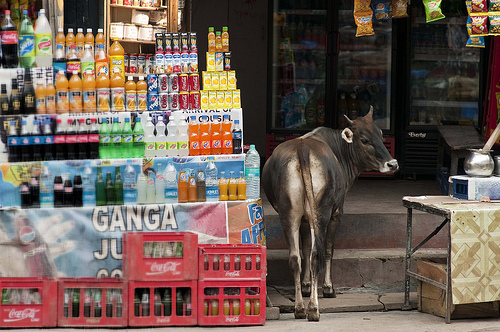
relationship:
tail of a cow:
[282, 142, 329, 264] [244, 91, 414, 329]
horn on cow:
[341, 110, 352, 122] [260, 105, 399, 322]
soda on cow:
[1, 1, 246, 201] [260, 105, 399, 322]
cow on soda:
[260, 105, 399, 322] [42, 71, 142, 107]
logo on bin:
[222, 267, 245, 278] [196, 243, 270, 289]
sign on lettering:
[3, 200, 228, 306] [90, 199, 182, 232]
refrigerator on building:
[265, 0, 402, 180] [16, 0, 376, 249]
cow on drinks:
[260, 105, 399, 322] [0, 1, 265, 323]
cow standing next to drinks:
[251, 82, 395, 302] [20, 42, 257, 297]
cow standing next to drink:
[260, 105, 399, 322] [240, 142, 265, 197]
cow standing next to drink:
[260, 105, 399, 322] [111, 162, 124, 203]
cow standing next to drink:
[260, 105, 399, 322] [107, 37, 126, 90]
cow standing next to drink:
[260, 105, 399, 322] [35, 9, 55, 69]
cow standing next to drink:
[260, 105, 399, 322] [50, 164, 64, 206]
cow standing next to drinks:
[260, 105, 399, 322] [2, 3, 262, 200]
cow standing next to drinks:
[260, 105, 399, 322] [31, 29, 237, 290]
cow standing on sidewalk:
[260, 105, 399, 322] [279, 289, 427, 326]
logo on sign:
[9, 222, 36, 246] [6, 305, 49, 323]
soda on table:
[98, 114, 112, 156] [10, 200, 271, 300]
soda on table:
[108, 115, 120, 157] [10, 200, 271, 300]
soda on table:
[187, 115, 199, 154] [10, 200, 271, 300]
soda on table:
[198, 117, 210, 152] [10, 200, 271, 300]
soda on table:
[153, 115, 166, 158] [10, 200, 271, 300]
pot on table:
[462, 141, 499, 176] [398, 181, 498, 298]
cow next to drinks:
[260, 105, 399, 322] [14, 21, 261, 327]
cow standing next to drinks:
[260, 105, 399, 322] [10, 13, 264, 253]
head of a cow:
[329, 99, 409, 180] [260, 105, 399, 322]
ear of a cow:
[341, 110, 351, 123] [225, 75, 410, 330]